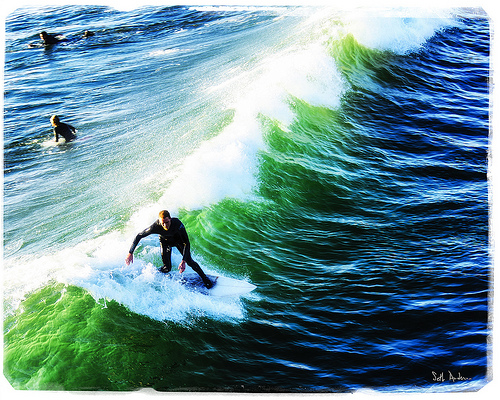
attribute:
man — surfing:
[130, 207, 210, 289]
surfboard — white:
[168, 269, 257, 298]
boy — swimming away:
[48, 112, 78, 143]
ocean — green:
[2, 282, 162, 391]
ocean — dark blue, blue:
[366, 68, 489, 360]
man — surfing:
[29, 29, 69, 55]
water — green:
[9, 282, 124, 399]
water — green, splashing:
[187, 106, 292, 233]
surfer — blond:
[130, 203, 193, 279]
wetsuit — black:
[55, 121, 74, 138]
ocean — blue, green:
[157, 33, 498, 255]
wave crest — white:
[188, 16, 344, 227]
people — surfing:
[27, 27, 82, 149]